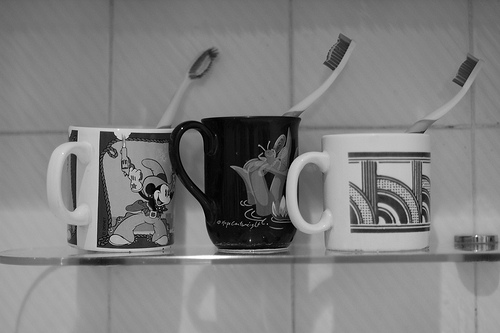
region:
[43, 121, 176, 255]
cup is next to cup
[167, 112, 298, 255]
cup is next to cup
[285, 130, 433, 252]
cup is next to cup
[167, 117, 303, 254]
mug is between two other mugs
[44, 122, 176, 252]
mug has toothbrush in it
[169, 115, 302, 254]
mug has toothbrush in it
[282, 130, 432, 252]
mug has toothbrush in it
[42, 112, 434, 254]
mugs are all facing the same direction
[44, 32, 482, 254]
all three mugs have toothbrushes in them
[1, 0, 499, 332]
wall is tiled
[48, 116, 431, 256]
Three cups are together.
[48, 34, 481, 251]
The cups are holding toothbrushes.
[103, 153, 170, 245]
Mickey Mouse is on the mug.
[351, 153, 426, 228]
A graphic pattern is on the mug.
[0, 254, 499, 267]
The mugs sit on a shelf.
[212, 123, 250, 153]
The mug is black.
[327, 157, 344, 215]
The mug is white.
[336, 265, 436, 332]
The mug's shadow is on the wall.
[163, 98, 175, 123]
The toothbrush is white.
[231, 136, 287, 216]
An image is on the mug.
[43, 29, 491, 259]
Three toothbrushes in mugs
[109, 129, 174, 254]
Mickey Mouse wearing a cowboy hat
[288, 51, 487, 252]
One toothbrush in a white mug with designs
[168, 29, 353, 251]
Toothbrush in a black mug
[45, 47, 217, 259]
Toothbrush in a Mickey Mouse mug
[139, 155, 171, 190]
Cowboy hat on Mickey Mouse's head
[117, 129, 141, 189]
Gun in Mickey Mouse's hand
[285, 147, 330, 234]
White handle on the mug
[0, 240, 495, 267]
Glass shelf on the wall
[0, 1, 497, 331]
Tile on the wall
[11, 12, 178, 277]
this is a cup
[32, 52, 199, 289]
this is a coffee cup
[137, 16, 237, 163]
this is a toothbrush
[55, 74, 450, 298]
this is a row of cups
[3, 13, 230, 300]
toothbrush in a cup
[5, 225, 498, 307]
this is a shelf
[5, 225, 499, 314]
the shelf is glass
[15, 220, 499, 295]
silver trim on shelf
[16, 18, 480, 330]
tile wall behind cups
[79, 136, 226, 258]
mickey mouse on cup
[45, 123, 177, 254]
ceramic mug on top of a glass shelf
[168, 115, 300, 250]
black mug next to a white mug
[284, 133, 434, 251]
mug to the right of a mug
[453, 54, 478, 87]
bristles attached to a toothbrush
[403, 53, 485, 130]
toothbrush is inside of a mug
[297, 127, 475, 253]
white tile behind mug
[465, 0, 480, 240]
grout line behind bristles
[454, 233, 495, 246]
silver disc on shelf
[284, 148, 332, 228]
handle attached to mug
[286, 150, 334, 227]
white handle touching black mug